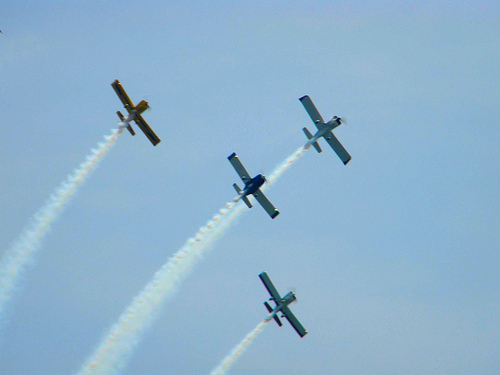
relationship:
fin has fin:
[302, 127, 323, 154] [301, 127, 323, 154]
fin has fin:
[263, 301, 282, 326] [262, 303, 282, 327]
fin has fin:
[232, 183, 253, 209] [229, 184, 255, 210]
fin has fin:
[116, 110, 137, 136] [117, 112, 137, 138]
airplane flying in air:
[227, 152, 280, 220] [5, 3, 490, 365]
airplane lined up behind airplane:
[227, 152, 280, 220] [298, 94, 352, 164]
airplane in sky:
[110, 79, 161, 146] [31, 6, 490, 346]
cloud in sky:
[74, 145, 310, 375] [3, 0, 499, 371]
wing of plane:
[280, 306, 307, 338] [260, 269, 308, 339]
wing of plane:
[296, 82, 330, 139] [281, 75, 367, 176]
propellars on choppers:
[333, 110, 348, 127] [298, 94, 353, 166]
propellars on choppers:
[258, 171, 270, 186] [226, 151, 281, 220]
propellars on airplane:
[141, 97, 153, 111] [110, 79, 161, 146]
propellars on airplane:
[289, 287, 299, 301] [258, 271, 308, 338]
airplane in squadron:
[110, 79, 161, 146] [110, 79, 350, 340]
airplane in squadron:
[227, 152, 280, 220] [110, 79, 350, 340]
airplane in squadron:
[298, 94, 352, 164] [110, 79, 350, 340]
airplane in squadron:
[258, 271, 308, 338] [110, 79, 350, 340]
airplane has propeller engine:
[106, 79, 158, 150] [335, 112, 345, 127]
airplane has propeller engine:
[296, 90, 353, 165] [259, 166, 267, 187]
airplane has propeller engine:
[221, 152, 280, 220] [139, 97, 148, 109]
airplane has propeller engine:
[256, 269, 309, 340] [289, 289, 299, 302]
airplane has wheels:
[298, 94, 352, 164] [312, 121, 335, 142]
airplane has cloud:
[110, 79, 161, 146] [74, 145, 310, 375]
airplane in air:
[110, 79, 161, 146] [50, 44, 379, 358]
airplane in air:
[258, 271, 308, 338] [48, 31, 408, 358]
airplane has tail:
[227, 152, 280, 220] [226, 174, 256, 214]